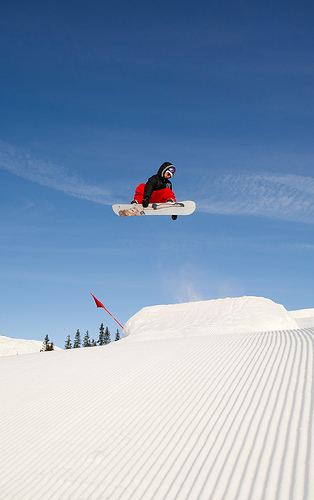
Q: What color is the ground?
A: White.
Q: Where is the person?
A: In the air.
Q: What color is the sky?
A: Blue with wispy clouds.